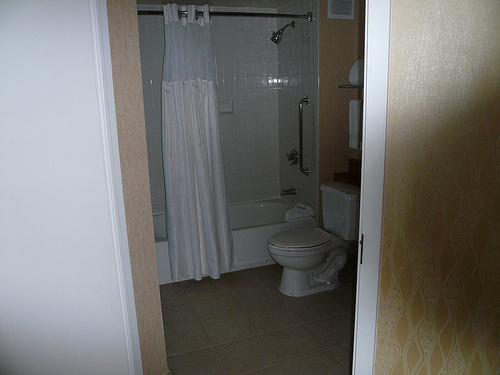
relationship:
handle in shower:
[287, 90, 322, 177] [146, 20, 316, 208]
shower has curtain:
[146, 20, 316, 208] [166, 22, 223, 221]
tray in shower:
[218, 92, 237, 118] [146, 20, 316, 208]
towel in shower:
[341, 101, 365, 149] [146, 20, 316, 208]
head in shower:
[269, 22, 291, 45] [146, 20, 316, 208]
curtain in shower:
[166, 22, 223, 221] [146, 20, 316, 208]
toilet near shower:
[272, 234, 347, 291] [146, 20, 316, 208]